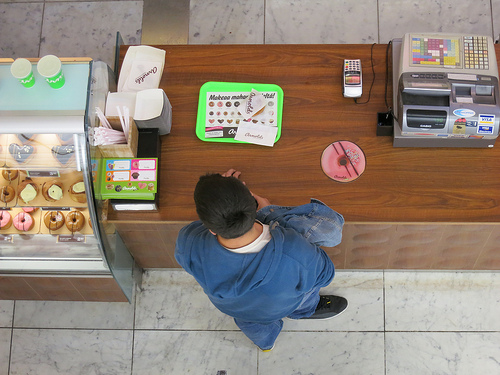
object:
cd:
[319, 141, 366, 183]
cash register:
[386, 28, 499, 148]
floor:
[371, 275, 474, 349]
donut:
[318, 138, 365, 182]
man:
[175, 165, 348, 350]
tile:
[386, 273, 498, 333]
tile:
[383, 331, 498, 372]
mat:
[195, 79, 288, 147]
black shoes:
[301, 292, 349, 321]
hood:
[191, 226, 285, 307]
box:
[97, 156, 159, 201]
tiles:
[246, 323, 383, 372]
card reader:
[339, 55, 362, 101]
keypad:
[340, 57, 359, 73]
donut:
[10, 212, 31, 232]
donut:
[0, 211, 10, 228]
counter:
[0, 53, 140, 304]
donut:
[43, 208, 64, 229]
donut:
[0, 183, 14, 202]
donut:
[65, 208, 84, 230]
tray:
[193, 77, 280, 149]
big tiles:
[281, 270, 383, 330]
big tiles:
[383, 271, 498, 330]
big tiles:
[258, 331, 384, 373]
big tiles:
[386, 331, 499, 372]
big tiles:
[131, 330, 258, 373]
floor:
[0, 0, 499, 67]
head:
[191, 172, 259, 242]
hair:
[191, 172, 257, 239]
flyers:
[97, 158, 159, 200]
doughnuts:
[41, 181, 63, 203]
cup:
[36, 54, 64, 91]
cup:
[9, 56, 37, 88]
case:
[0, 55, 142, 307]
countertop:
[110, 38, 500, 221]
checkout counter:
[101, 38, 500, 273]